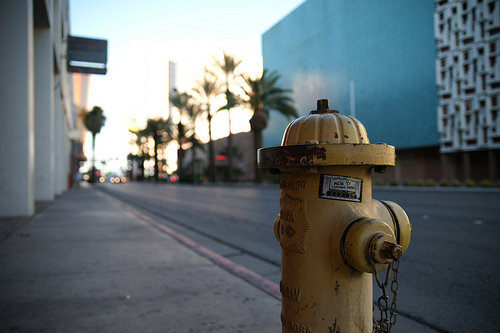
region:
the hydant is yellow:
[252, 102, 414, 332]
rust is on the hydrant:
[251, 132, 319, 179]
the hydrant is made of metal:
[268, 98, 425, 332]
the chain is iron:
[369, 262, 409, 332]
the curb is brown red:
[181, 234, 263, 289]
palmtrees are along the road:
[158, 61, 273, 186]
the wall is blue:
[263, 31, 429, 128]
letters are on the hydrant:
[273, 283, 311, 302]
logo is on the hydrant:
[261, 193, 314, 261]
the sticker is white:
[319, 168, 367, 203]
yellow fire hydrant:
[255, 97, 413, 331]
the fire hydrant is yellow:
[255, 99, 413, 331]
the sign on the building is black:
[65, 34, 108, 74]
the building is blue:
[260, 0, 499, 187]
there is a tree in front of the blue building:
[236, 69, 299, 183]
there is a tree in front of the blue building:
[213, 51, 248, 183]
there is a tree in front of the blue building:
[192, 66, 225, 184]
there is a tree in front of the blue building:
[167, 86, 194, 182]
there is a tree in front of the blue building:
[144, 117, 174, 182]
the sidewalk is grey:
[1, 181, 282, 331]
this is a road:
[172, 192, 228, 259]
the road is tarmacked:
[145, 192, 240, 248]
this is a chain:
[380, 292, 397, 328]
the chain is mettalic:
[372, 288, 397, 328]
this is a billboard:
[65, 39, 108, 72]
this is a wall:
[305, 33, 424, 70]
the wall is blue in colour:
[307, 41, 387, 78]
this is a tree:
[247, 77, 278, 139]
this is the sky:
[139, 23, 227, 44]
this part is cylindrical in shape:
[265, 146, 397, 169]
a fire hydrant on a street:
[21, 18, 461, 313]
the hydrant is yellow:
[265, 99, 425, 326]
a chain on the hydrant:
[338, 207, 413, 331]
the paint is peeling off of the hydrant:
[238, 90, 399, 194]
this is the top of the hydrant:
[228, 72, 402, 170]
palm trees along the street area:
[88, 57, 306, 154]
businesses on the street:
[18, 5, 94, 225]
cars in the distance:
[83, 162, 151, 204]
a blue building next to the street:
[251, 15, 482, 153]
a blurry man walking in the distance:
[68, 163, 88, 188]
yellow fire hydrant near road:
[272, 102, 395, 329]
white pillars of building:
[2, 35, 67, 169]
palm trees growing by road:
[130, 60, 290, 156]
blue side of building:
[248, 27, 432, 163]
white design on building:
[434, 16, 499, 161]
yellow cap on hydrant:
[354, 222, 408, 278]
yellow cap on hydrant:
[390, 201, 412, 250]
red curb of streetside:
[118, 205, 244, 270]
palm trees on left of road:
[78, 92, 113, 169]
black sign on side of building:
[67, 30, 112, 82]